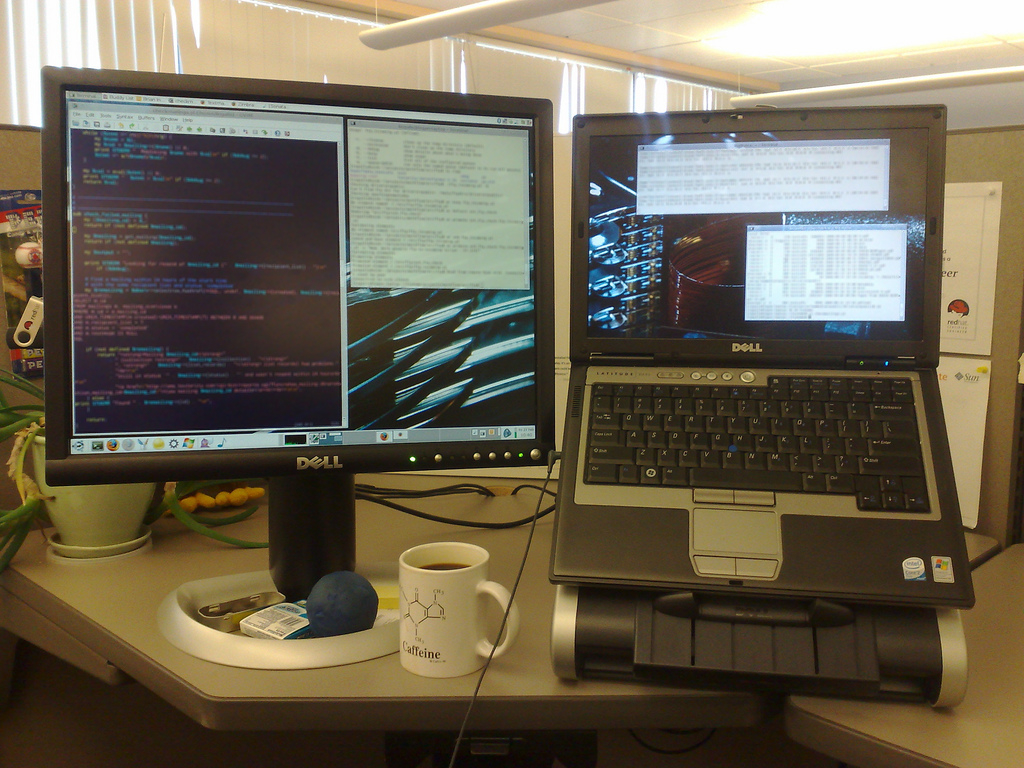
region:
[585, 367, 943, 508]
keys on the laptop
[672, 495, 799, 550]
mouse pad on the laptop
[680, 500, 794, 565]
The mouse pad is grey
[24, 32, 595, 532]
a black dell computer monitor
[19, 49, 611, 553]
a flat-screen monitor for computer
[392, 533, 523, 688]
A white mug on the desk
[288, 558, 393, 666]
a blue ball on the desk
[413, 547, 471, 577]
coffee in the mug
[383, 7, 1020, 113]
ceiling with glowing light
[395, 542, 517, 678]
coffee cup with handle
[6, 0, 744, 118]
vertical blinds on windows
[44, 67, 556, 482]
image on computer monitor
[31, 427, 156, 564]
planter on round base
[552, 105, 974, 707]
open laptop on stand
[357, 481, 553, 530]
black wires above tabletop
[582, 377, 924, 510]
buttons of computer keyboard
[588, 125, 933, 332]
glowing image on screen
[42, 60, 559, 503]
a black computer monitor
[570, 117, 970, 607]
a laptop with the lid open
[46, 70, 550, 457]
a monitor that is turned on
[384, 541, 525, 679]
a coffee mug with a beverage in it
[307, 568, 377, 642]
a blue hand stress ball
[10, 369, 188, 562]
a plant in a pot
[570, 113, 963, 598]
a laptop that is switched on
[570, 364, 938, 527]
a black and grey laptop keyboard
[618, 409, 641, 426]
A key on a keyboard.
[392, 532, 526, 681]
white coffee cup on desk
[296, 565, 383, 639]
blue squeeze stress ball on desk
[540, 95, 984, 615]
upright laptop on desk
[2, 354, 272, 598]
potted flower on desk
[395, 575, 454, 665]
black design on front of coffee cup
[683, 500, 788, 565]
grey track pad on front of laptop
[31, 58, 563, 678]
black monitor on desk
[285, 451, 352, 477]
monitor logo name on monitor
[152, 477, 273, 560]
green leaf of potted plant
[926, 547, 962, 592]
silver sticker on front of laptop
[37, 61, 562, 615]
black screen on top of gray desk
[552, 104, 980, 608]
black laptop on top of gray desk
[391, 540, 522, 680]
white coffee cup on top of gray desk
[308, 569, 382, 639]
blue round ball under black screen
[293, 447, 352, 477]
gray dell letters on black screen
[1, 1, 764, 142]
white curtains hanging in the background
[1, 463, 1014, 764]
gray desk on white office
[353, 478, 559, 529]
black wires behind screen and laptop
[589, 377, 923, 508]
black keys on laptop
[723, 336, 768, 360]
gray dell letters on top of black laptop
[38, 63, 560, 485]
A black framed computer monitor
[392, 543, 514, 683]
A white cup on a desk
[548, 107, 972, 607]
A black laptop on a desk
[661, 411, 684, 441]
A key on a keyboard.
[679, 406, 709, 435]
A key on a keyboard.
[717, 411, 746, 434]
A key on a keyboard.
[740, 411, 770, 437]
A key on a keyboard.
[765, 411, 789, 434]
A key on a keyboard.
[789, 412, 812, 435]
A key on a keyboard.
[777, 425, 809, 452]
A key on a keyboard.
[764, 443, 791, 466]
A key on a keyboard.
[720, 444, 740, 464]
A key on a keyboard.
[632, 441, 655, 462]
A key on a keyboard.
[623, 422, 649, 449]
A key on a keyboard.